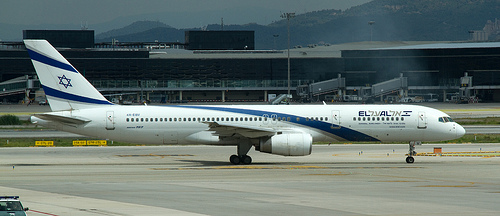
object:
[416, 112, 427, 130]
plane has door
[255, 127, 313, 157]
plane has engine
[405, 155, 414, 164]
plane has wheel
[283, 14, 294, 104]
pole is tall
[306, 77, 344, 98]
tunnel is gray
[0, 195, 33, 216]
vehicle is on runway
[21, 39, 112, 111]
plane has tail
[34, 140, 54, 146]
sign is yellow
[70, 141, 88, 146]
sign is small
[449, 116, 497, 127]
grass is green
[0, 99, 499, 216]
airport has tarmac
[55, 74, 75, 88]
plane has star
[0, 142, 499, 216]
airport has runway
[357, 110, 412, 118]
plane has logo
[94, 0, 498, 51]
mountain in distance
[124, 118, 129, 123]
plane has window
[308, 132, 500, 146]
grass is on runway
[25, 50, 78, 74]
stripe is blue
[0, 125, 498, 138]
airport has roadway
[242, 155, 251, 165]
plane has tire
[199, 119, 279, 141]
plane has wing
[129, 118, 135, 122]
plane has window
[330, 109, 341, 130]
plane has door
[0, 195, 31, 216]
police in vehicle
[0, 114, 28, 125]
grass is on runway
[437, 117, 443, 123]
plane has windshield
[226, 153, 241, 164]
plane has wheel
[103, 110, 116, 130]
plane has door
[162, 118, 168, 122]
plane has window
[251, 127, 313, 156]
plane has jet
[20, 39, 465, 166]
airplane